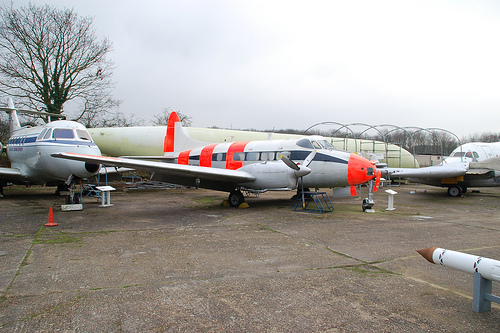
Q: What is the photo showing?
A: It is showing a pavement.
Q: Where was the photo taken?
A: It was taken at the pavement.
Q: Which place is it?
A: It is a pavement.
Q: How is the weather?
A: It is cloudy.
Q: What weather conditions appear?
A: It is cloudy.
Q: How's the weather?
A: It is cloudy.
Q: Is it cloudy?
A: Yes, it is cloudy.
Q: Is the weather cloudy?
A: Yes, it is cloudy.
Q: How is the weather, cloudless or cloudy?
A: It is cloudy.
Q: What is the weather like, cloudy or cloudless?
A: It is cloudy.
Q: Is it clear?
A: No, it is cloudy.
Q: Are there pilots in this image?
A: No, there are no pilots.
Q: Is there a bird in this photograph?
A: No, there are no birds.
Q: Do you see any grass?
A: Yes, there is grass.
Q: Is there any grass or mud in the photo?
A: Yes, there is grass.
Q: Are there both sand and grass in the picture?
A: No, there is grass but no sand.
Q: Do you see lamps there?
A: No, there are no lamps.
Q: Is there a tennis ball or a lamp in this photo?
A: No, there are no lamps or tennis balls.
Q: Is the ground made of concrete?
A: Yes, the ground is made of concrete.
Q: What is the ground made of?
A: The ground is made of concrete.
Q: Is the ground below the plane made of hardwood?
A: No, the ground is made of concrete.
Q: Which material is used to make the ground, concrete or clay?
A: The ground is made of concrete.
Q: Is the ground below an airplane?
A: Yes, the ground is below an airplane.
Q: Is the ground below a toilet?
A: No, the ground is below an airplane.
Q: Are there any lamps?
A: No, there are no lamps.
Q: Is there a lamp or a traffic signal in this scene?
A: No, there are no lamps or traffic lights.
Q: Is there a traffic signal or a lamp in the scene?
A: No, there are no lamps or traffic lights.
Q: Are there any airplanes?
A: Yes, there is an airplane.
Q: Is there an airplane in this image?
A: Yes, there is an airplane.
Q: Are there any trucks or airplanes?
A: Yes, there is an airplane.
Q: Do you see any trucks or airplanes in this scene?
A: Yes, there is an airplane.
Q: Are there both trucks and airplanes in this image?
A: No, there is an airplane but no trucks.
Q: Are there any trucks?
A: No, there are no trucks.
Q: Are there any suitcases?
A: No, there are no suitcases.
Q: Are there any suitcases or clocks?
A: No, there are no suitcases or clocks.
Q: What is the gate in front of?
A: The gate is in front of the airplane.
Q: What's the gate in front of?
A: The gate is in front of the airplane.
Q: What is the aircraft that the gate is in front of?
A: The aircraft is an airplane.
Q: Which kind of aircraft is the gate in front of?
A: The gate is in front of the plane.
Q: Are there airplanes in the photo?
A: Yes, there is an airplane.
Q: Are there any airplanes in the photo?
A: Yes, there is an airplane.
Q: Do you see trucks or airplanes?
A: Yes, there is an airplane.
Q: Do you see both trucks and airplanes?
A: No, there is an airplane but no trucks.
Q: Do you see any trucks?
A: No, there are no trucks.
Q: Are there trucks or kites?
A: No, there are no trucks or kites.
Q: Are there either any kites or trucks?
A: No, there are no trucks or kites.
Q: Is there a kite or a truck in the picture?
A: No, there are no trucks or kites.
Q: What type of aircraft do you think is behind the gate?
A: The aircraft is an airplane.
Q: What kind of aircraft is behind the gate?
A: The aircraft is an airplane.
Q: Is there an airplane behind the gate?
A: Yes, there is an airplane behind the gate.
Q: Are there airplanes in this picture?
A: Yes, there is an airplane.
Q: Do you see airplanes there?
A: Yes, there is an airplane.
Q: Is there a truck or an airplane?
A: Yes, there is an airplane.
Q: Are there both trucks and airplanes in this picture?
A: No, there is an airplane but no trucks.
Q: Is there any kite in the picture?
A: No, there are no kites.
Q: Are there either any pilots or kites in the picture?
A: No, there are no kites or pilots.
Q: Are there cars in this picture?
A: No, there are no cars.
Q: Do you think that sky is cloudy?
A: Yes, the sky is cloudy.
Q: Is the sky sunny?
A: No, the sky is cloudy.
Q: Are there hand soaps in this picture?
A: No, there are no hand soaps.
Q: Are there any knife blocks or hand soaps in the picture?
A: No, there are no hand soaps or knife blocks.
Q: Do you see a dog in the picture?
A: No, there are no dogs.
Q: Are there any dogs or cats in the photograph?
A: No, there are no dogs or cats.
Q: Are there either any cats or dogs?
A: No, there are no dogs or cats.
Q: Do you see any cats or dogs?
A: No, there are no dogs or cats.